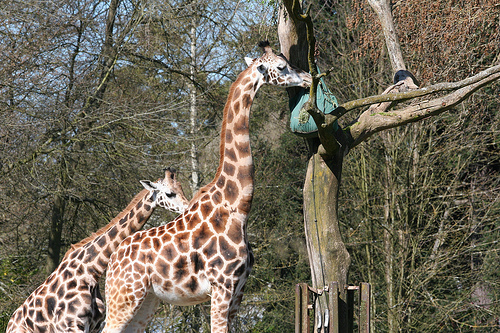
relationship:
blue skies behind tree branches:
[184, 1, 236, 74] [18, 14, 202, 141]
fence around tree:
[294, 280, 372, 330] [279, 3, 499, 331]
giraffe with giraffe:
[7, 167, 189, 331] [102, 40, 312, 329]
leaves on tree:
[342, 1, 498, 85] [279, 3, 499, 331]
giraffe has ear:
[7, 167, 189, 331] [136, 176, 160, 191]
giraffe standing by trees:
[7, 167, 189, 331] [0, 1, 498, 331]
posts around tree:
[294, 280, 372, 330] [279, 3, 499, 331]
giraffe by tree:
[102, 40, 312, 329] [279, 3, 499, 331]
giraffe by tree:
[7, 167, 189, 331] [279, 3, 499, 331]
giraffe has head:
[102, 40, 312, 329] [247, 39, 313, 90]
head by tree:
[247, 39, 313, 90] [279, 3, 499, 331]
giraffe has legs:
[102, 40, 312, 329] [100, 269, 248, 330]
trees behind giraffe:
[0, 1, 498, 331] [102, 40, 312, 329]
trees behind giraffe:
[0, 1, 498, 331] [7, 167, 189, 331]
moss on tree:
[274, 1, 496, 329] [279, 3, 499, 331]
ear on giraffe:
[136, 176, 160, 191] [7, 167, 189, 331]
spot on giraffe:
[190, 219, 213, 248] [102, 40, 312, 329]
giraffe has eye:
[102, 40, 312, 329] [275, 64, 289, 74]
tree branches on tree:
[18, 14, 202, 141] [0, 0, 129, 219]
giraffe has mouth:
[102, 40, 312, 329] [301, 69, 311, 89]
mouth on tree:
[301, 69, 311, 89] [279, 3, 499, 331]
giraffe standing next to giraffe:
[7, 167, 189, 331] [102, 40, 312, 329]